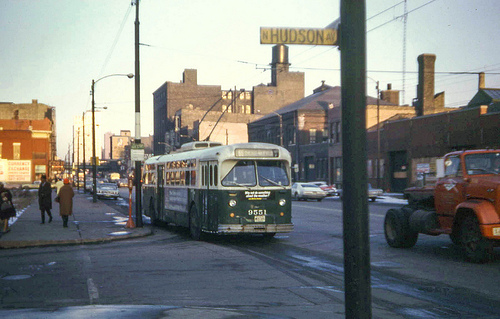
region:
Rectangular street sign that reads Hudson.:
[262, 23, 333, 48]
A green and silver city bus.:
[138, 133, 295, 234]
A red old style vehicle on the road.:
[379, 149, 499, 243]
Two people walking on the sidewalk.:
[30, 168, 75, 226]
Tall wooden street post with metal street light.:
[87, 66, 134, 192]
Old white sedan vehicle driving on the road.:
[290, 176, 328, 200]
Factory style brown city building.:
[151, 28, 318, 159]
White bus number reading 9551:
[240, 206, 272, 216]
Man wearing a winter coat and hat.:
[36, 173, 53, 225]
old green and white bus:
[120, 136, 300, 231]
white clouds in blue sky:
[55, 25, 79, 40]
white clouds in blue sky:
[44, 42, 88, 67]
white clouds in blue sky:
[155, 8, 190, 59]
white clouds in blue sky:
[194, 18, 232, 59]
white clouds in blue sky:
[384, 11, 416, 55]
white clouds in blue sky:
[421, 1, 498, 56]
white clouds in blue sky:
[30, 19, 102, 53]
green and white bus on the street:
[135, 137, 297, 242]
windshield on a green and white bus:
[219, 159, 291, 191]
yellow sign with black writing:
[255, 20, 347, 54]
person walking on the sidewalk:
[52, 176, 79, 232]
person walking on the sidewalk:
[36, 170, 54, 229]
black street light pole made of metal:
[127, 2, 148, 231]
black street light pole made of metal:
[337, 2, 375, 317]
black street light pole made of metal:
[85, 72, 102, 204]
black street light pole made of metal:
[80, 109, 87, 196]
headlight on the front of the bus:
[277, 194, 289, 208]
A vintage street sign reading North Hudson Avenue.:
[246, 8, 384, 67]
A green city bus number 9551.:
[126, 140, 316, 250]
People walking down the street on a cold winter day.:
[21, 152, 98, 259]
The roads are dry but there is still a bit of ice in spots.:
[29, 144, 345, 317]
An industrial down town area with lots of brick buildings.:
[149, 37, 446, 248]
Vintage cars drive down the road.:
[291, 152, 347, 224]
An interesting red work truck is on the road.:
[378, 131, 495, 275]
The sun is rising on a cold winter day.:
[0, 13, 195, 296]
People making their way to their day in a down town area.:
[34, 61, 448, 300]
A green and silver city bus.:
[145, 152, 291, 234]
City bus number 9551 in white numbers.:
[247, 206, 268, 220]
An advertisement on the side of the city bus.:
[160, 182, 194, 215]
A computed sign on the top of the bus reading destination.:
[232, 147, 274, 160]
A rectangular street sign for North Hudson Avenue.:
[256, 23, 340, 49]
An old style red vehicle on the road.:
[387, 144, 498, 264]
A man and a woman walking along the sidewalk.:
[28, 170, 78, 224]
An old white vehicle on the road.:
[290, 172, 326, 197]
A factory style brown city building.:
[152, 62, 302, 139]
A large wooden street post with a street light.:
[87, 67, 139, 203]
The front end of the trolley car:
[209, 141, 296, 240]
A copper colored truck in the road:
[384, 139, 497, 269]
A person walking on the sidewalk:
[56, 173, 77, 233]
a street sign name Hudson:
[255, 21, 351, 49]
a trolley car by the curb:
[140, 142, 302, 235]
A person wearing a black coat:
[30, 169, 56, 226]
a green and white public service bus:
[139, 138, 291, 244]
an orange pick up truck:
[379, 144, 497, 261]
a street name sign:
[258, 24, 338, 46]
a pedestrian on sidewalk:
[55, 176, 77, 226]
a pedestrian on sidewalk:
[38, 174, 55, 221]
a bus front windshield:
[256, 159, 288, 186]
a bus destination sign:
[235, 147, 273, 157]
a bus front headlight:
[229, 199, 235, 204]